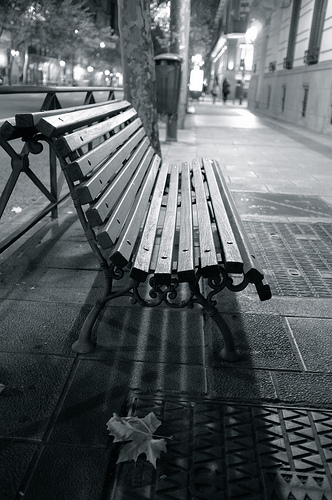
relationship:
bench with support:
[45, 88, 279, 359] [32, 134, 256, 376]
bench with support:
[45, 88, 279, 359] [133, 167, 226, 233]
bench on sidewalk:
[45, 88, 279, 359] [0, 101, 331, 498]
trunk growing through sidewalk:
[116, 1, 161, 165] [0, 101, 331, 498]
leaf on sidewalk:
[107, 409, 174, 467] [0, 101, 331, 498]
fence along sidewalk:
[0, 88, 116, 252] [147, 87, 330, 380]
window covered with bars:
[301, 0, 328, 63] [282, 0, 296, 66]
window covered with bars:
[301, 0, 328, 63] [307, 0, 322, 63]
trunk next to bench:
[116, 1, 161, 165] [0, 96, 272, 371]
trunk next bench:
[116, 1, 161, 165] [0, 96, 272, 371]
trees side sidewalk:
[35, 15, 114, 62] [2, 99, 331, 500]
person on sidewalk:
[219, 72, 234, 107] [147, 55, 324, 151]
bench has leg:
[0, 96, 272, 371] [193, 293, 250, 369]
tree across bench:
[115, 0, 186, 150] [0, 96, 272, 371]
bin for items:
[150, 40, 189, 124] [159, 62, 173, 97]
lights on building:
[245, 20, 261, 43] [233, 0, 330, 138]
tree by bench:
[115, 0, 160, 150] [0, 96, 272, 371]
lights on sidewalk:
[10, 48, 115, 75] [2, 99, 331, 500]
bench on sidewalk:
[0, 96, 272, 371] [15, 75, 321, 434]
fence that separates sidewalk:
[0, 88, 116, 252] [2, 99, 330, 420]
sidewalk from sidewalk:
[2, 99, 330, 420] [2, 99, 331, 500]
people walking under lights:
[196, 66, 251, 112] [245, 20, 261, 43]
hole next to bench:
[155, 379, 302, 478] [63, 108, 246, 264]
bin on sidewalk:
[155, 55, 184, 118] [2, 99, 331, 500]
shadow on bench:
[28, 284, 258, 411] [0, 96, 272, 371]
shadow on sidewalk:
[28, 284, 258, 411] [2, 99, 331, 500]